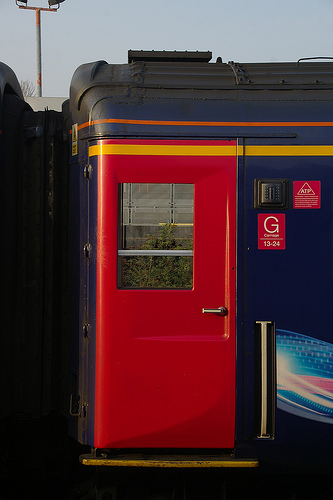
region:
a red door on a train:
[87, 135, 241, 452]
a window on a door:
[114, 174, 197, 291]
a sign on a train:
[252, 211, 286, 253]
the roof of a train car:
[74, 55, 331, 97]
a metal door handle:
[200, 304, 226, 322]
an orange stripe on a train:
[64, 104, 330, 132]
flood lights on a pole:
[12, 1, 70, 71]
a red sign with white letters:
[255, 211, 288, 253]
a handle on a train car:
[251, 314, 280, 447]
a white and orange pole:
[30, 13, 56, 87]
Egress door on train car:
[86, 133, 243, 449]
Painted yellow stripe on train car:
[87, 141, 331, 158]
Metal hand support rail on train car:
[253, 318, 272, 441]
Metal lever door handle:
[202, 305, 227, 315]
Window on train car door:
[113, 178, 200, 292]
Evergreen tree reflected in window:
[116, 219, 192, 288]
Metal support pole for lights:
[10, 1, 62, 96]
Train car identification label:
[257, 214, 284, 251]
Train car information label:
[289, 179, 324, 208]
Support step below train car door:
[82, 458, 263, 471]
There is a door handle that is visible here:
[199, 296, 224, 322]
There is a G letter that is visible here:
[256, 209, 290, 268]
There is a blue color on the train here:
[256, 284, 272, 305]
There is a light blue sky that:
[235, 18, 257, 59]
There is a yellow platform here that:
[186, 453, 217, 487]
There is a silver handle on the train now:
[253, 322, 301, 473]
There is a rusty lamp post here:
[28, 11, 54, 63]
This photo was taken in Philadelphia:
[88, 75, 297, 399]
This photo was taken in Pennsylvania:
[75, 26, 295, 485]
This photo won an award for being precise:
[69, 143, 292, 490]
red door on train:
[106, 159, 224, 438]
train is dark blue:
[252, 247, 329, 322]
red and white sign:
[256, 201, 280, 249]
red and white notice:
[289, 181, 330, 226]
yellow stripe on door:
[96, 134, 249, 157]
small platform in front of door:
[83, 449, 255, 478]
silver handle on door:
[200, 299, 222, 325]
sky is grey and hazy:
[87, 5, 158, 38]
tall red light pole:
[4, 4, 57, 81]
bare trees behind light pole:
[22, 67, 41, 97]